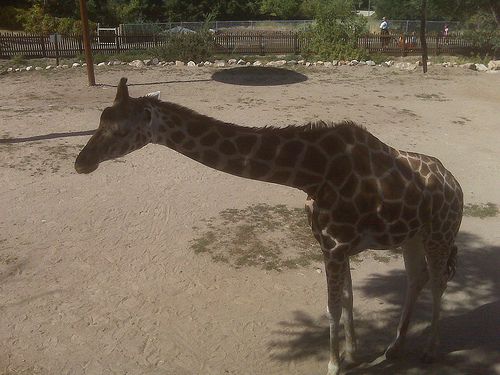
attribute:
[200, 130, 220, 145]
spot — brown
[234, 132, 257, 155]
spot — brown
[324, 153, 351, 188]
spot — brown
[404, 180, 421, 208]
spot — brown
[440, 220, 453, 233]
spot — brown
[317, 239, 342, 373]
leg — skinny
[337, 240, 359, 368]
leg — skinny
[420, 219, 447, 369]
leg — skinny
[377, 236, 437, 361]
leg — skinny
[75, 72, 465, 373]
giraffe — baby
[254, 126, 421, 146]
hair — sticking up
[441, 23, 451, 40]
children — visiting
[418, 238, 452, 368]
leg — giraffe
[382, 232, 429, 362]
leg — giraffe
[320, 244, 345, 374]
leg — giraffe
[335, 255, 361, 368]
leg — giraffe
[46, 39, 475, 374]
giraffe — standing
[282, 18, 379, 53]
bush — green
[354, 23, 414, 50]
mother — visiting